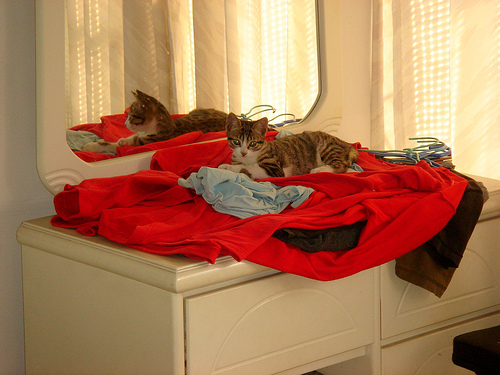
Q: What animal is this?
A: Kitten.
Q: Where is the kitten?
A: On top of the shirts.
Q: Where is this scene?
A: Inside a bedroom.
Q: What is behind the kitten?
A: A mirror.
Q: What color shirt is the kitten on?
A: Orange.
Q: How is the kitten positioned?
A: Lying down.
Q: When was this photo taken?
A: During the day.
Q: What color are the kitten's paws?
A: White.